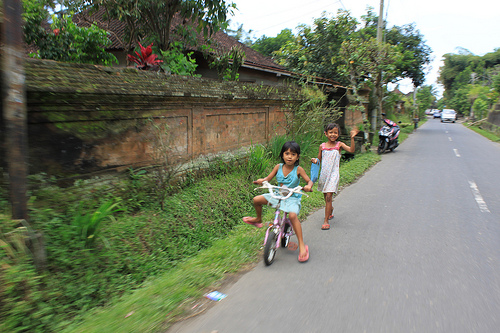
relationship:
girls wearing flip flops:
[243, 141, 313, 261] [243, 214, 313, 262]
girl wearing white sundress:
[311, 123, 360, 230] [319, 149, 344, 202]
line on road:
[464, 173, 487, 228] [396, 204, 461, 312]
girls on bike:
[242, 141, 313, 262] [227, 179, 345, 266]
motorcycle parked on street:
[378, 113, 402, 155] [361, 115, 462, 330]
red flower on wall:
[130, 40, 162, 70] [23, 59, 372, 181]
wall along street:
[0, 9, 385, 264] [159, 87, 499, 331]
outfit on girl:
[249, 157, 327, 221] [235, 127, 375, 249]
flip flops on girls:
[241, 213, 313, 265] [242, 141, 313, 262]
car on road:
[433, 109, 442, 118] [378, 133, 491, 279]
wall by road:
[0, 107, 295, 229] [148, 115, 498, 330]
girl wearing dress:
[311, 123, 360, 230] [317, 141, 342, 194]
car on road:
[440, 107, 458, 121] [148, 115, 498, 330]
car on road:
[433, 107, 443, 117] [148, 115, 498, 330]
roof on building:
[140, 1, 378, 91] [61, 0, 380, 90]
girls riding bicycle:
[242, 141, 313, 262] [253, 178, 309, 264]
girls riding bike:
[242, 141, 313, 262] [252, 181, 313, 266]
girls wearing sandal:
[242, 141, 313, 262] [295, 241, 310, 263]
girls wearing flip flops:
[242, 141, 313, 262] [242, 216, 262, 228]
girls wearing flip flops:
[242, 141, 313, 262] [298, 244, 309, 262]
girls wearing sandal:
[242, 141, 313, 262] [242, 214, 262, 226]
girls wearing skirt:
[242, 141, 313, 262] [262, 191, 307, 215]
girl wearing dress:
[300, 114, 380, 234] [319, 141, 346, 196]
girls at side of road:
[242, 141, 313, 262] [182, 118, 499, 332]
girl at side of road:
[311, 123, 360, 230] [182, 118, 499, 332]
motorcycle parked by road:
[373, 108, 407, 155] [395, 132, 450, 232]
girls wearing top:
[242, 141, 313, 262] [273, 162, 300, 198]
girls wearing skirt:
[242, 141, 313, 262] [260, 191, 302, 217]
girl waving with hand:
[311, 123, 360, 230] [346, 125, 362, 136]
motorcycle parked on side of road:
[378, 113, 402, 155] [148, 115, 498, 330]